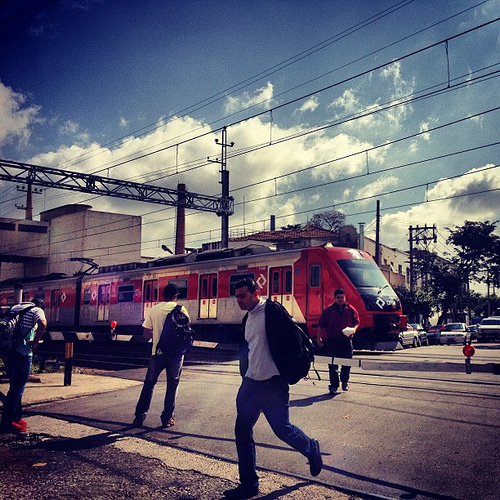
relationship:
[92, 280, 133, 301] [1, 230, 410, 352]
window on train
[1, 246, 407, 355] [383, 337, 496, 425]
train on tracks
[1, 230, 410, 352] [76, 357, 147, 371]
train on tracks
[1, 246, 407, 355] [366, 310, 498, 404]
train on tracks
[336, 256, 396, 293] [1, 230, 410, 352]
window on a train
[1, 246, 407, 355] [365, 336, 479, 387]
train on track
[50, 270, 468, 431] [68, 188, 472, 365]
track with train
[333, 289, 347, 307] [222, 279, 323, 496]
head of man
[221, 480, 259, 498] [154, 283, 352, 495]
foot of person